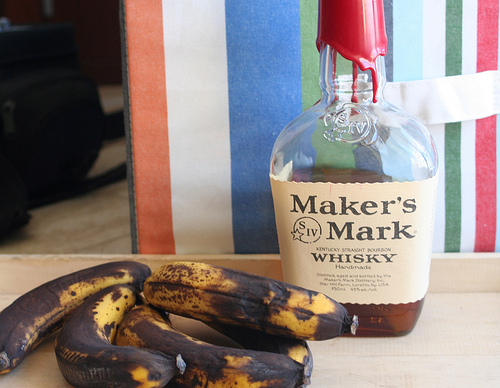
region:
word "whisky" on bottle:
[308, 248, 402, 267]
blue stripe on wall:
[226, 0, 308, 250]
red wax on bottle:
[315, 2, 387, 99]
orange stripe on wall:
[129, 1, 174, 254]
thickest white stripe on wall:
[161, 0, 231, 253]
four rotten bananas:
[3, 260, 322, 387]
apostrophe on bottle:
[391, 195, 404, 206]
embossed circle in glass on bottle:
[326, 100, 376, 150]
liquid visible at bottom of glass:
[341, 297, 428, 332]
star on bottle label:
[288, 227, 304, 242]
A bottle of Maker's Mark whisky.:
[262, 40, 443, 346]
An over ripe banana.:
[0, 256, 128, 375]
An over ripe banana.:
[51, 282, 189, 386]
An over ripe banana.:
[122, 299, 312, 385]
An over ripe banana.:
[141, 260, 368, 344]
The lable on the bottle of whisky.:
[266, 176, 444, 303]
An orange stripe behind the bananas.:
[122, 5, 179, 253]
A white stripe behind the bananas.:
[164, 3, 236, 254]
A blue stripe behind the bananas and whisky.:
[226, 3, 289, 255]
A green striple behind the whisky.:
[298, 5, 353, 179]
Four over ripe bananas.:
[2, 240, 360, 386]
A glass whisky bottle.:
[262, 3, 462, 330]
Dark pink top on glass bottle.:
[308, 2, 393, 104]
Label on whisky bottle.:
[263, 157, 438, 312]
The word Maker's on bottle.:
[283, 185, 416, 220]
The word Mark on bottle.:
[317, 217, 422, 242]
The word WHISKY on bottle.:
[302, 251, 401, 266]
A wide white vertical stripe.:
[164, 10, 236, 255]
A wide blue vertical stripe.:
[226, 4, 302, 256]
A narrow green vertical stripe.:
[443, 3, 465, 254]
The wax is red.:
[305, 1, 404, 106]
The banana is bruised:
[5, 214, 362, 386]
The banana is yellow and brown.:
[0, 245, 360, 386]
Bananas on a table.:
[0, 226, 495, 386]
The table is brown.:
[2, 225, 493, 385]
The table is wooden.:
[0, 235, 498, 387]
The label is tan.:
[265, 153, 439, 310]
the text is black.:
[264, 163, 439, 309]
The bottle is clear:
[260, 1, 438, 341]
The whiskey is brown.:
[272, 152, 425, 344]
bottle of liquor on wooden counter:
[265, 2, 459, 344]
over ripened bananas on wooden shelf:
[27, 235, 304, 386]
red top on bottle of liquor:
[278, 1, 443, 312]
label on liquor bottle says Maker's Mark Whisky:
[250, 155, 468, 316]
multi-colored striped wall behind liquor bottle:
[102, 4, 486, 264]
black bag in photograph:
[2, 18, 157, 249]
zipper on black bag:
[4, 92, 36, 157]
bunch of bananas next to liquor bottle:
[42, 1, 433, 386]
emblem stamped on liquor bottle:
[310, 91, 384, 153]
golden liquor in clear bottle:
[241, 2, 446, 354]